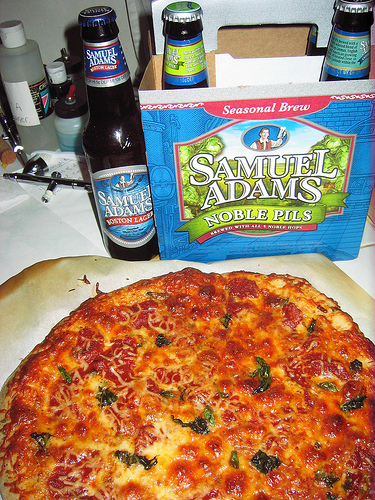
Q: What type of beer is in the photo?
A: Sam Adams.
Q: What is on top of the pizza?
A: Cheese.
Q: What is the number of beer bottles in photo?
A: Three.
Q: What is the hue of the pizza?
A: Red and orange.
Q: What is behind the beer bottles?
A: Bottles.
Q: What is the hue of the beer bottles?
A: Brown.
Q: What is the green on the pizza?
A: Vegetables.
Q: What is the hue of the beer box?
A: Blue and green.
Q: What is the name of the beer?
A: Samuel Adams.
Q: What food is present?
A: Pizza.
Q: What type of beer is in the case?
A: Noble Pils.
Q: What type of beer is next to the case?
A: Boston Lager.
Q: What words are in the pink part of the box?
A: Seasonal Brew.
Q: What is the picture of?
A: Pizza and beer.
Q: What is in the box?
A: 2 beer bottles.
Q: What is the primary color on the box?
A: Blue.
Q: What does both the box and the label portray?
A: A man holding a beer mug up.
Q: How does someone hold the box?
A: Handle.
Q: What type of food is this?
A: Pizza.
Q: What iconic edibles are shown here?
A: Pizza and beer.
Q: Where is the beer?
A: Behind the pizza.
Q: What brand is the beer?
A: Samuel Adams.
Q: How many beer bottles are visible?
A: Three.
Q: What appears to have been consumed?
A: Nothing yet.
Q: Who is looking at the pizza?
A: The photographer.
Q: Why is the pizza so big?
A: It's meant to be eaten by more than one person.